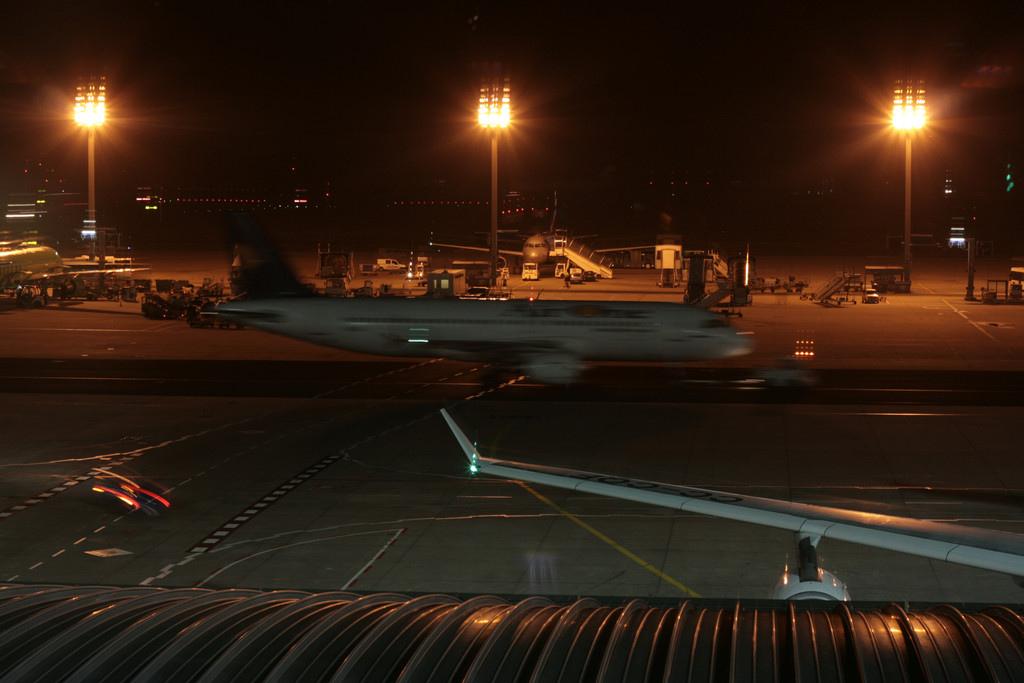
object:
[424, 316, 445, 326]
windows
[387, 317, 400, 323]
windows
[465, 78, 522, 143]
light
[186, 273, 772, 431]
plane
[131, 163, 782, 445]
plane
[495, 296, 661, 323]
name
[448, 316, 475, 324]
windows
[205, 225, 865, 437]
plane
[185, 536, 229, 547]
lines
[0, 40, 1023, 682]
airport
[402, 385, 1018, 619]
wing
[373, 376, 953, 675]
plane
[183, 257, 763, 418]
plane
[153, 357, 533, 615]
concrete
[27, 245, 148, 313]
loading truck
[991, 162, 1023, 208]
light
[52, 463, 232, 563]
stand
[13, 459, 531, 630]
road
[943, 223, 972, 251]
sign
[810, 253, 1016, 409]
road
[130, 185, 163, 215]
sign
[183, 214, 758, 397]
airplane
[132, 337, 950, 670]
runway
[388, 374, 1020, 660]
plane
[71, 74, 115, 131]
lights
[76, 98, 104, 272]
pole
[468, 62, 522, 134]
light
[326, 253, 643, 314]
runway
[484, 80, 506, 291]
pole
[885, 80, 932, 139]
light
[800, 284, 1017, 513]
runway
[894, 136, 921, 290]
pole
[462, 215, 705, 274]
plane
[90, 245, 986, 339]
ground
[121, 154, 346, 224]
buildings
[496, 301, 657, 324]
writing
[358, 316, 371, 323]
windows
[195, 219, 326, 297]
tail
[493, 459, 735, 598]
line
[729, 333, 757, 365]
nose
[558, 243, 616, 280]
stairs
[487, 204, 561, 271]
plane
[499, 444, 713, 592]
stripe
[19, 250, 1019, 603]
ground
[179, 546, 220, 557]
dashes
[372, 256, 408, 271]
van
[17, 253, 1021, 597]
tarmac